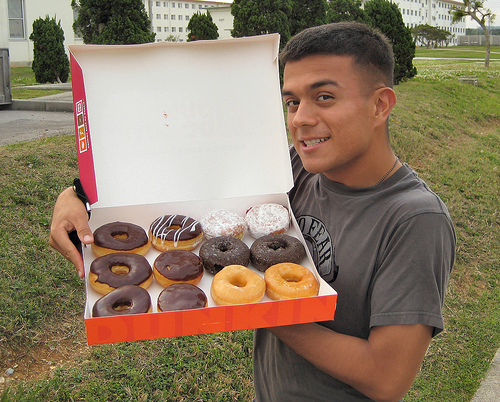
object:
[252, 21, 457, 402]
he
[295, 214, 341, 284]
logo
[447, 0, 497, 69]
tree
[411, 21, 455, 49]
tree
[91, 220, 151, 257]
donut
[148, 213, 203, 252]
donut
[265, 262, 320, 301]
donut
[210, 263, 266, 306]
donut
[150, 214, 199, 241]
chocolate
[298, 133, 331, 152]
mouth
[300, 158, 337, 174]
chin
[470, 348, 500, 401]
sidewalk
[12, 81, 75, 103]
sidewalk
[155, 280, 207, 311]
donut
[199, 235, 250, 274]
donut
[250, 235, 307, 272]
donut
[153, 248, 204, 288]
donut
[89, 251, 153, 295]
donut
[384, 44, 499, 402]
grass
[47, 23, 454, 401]
boy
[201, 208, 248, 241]
donut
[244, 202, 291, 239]
donut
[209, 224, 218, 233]
powder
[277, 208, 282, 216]
powder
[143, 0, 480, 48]
building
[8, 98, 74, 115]
curb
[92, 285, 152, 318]
donut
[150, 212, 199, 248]
frosting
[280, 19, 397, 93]
hair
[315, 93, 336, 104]
eye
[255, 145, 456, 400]
shirt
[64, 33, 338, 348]
box